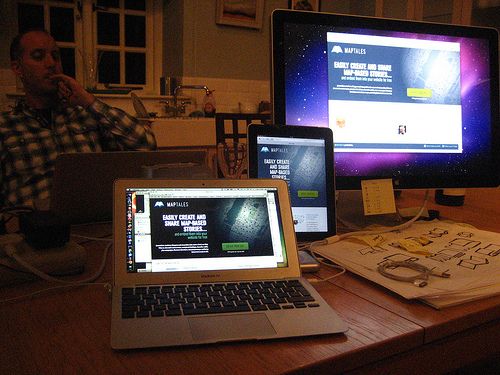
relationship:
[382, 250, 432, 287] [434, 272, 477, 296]
usb cord on top of paper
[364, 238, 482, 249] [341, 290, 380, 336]
paper on top of table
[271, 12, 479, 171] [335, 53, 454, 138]
monitor has advertising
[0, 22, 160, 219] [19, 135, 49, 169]
man wearing a shirt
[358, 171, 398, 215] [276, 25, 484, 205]
note on computer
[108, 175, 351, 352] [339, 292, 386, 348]
computers on table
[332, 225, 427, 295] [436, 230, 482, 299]
cables are on papers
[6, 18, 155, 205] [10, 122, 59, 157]
man wears plaid